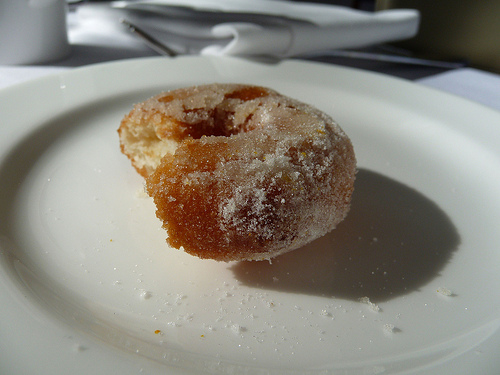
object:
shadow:
[226, 167, 463, 303]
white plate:
[0, 55, 500, 375]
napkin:
[105, 0, 420, 59]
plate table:
[0, 0, 499, 373]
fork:
[120, 18, 178, 57]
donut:
[117, 83, 355, 262]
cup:
[0, 0, 73, 65]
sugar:
[280, 197, 286, 203]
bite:
[117, 113, 179, 181]